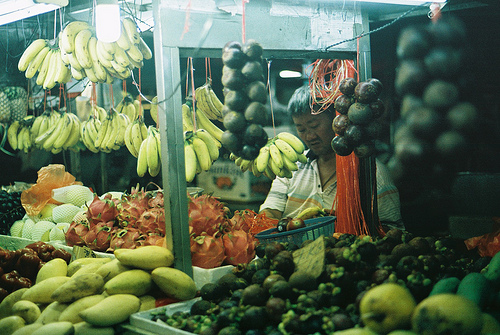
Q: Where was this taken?
A: Market.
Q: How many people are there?
A: 1.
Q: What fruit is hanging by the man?
A: Bananas.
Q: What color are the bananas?
A: Yellow.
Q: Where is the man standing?
A: Behind the fruit stand.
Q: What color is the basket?
A: Blue.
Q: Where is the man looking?
A: Down.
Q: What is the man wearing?
A: White, blue, yellow and orange shirt.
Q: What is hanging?
A: Bunches of yellow bananas.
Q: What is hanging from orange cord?
A: Round dark green fruit.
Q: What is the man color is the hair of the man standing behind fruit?
A: Black and grey.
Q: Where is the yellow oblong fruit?
A: On a fruit stand.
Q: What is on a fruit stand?
A: Red dragon fruit.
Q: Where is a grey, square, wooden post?
A: In the middle of the fruit.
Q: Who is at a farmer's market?
A: An Asian man.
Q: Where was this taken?
A: Market.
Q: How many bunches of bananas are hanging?
A: 15.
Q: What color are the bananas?
A: Yellow.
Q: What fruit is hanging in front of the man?
A: Banana.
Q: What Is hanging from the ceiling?
A: Bananas.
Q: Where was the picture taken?
A: The market.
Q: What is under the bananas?
A: Mangos.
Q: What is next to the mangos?
A: Avocados.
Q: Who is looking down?
A: The man.